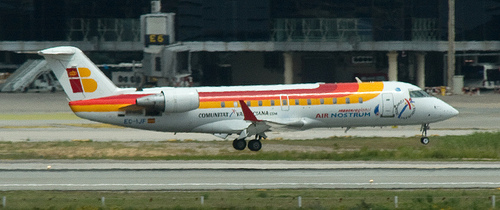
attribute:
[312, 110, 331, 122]
air — red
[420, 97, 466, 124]
nose — pointy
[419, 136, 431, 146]
wheel — plane, down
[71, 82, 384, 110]
stripe — yellow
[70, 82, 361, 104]
stripe — red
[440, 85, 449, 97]
can — yellow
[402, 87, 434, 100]
window — wraparound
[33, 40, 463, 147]
plane — landing, white, taking off, from spain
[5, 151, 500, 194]
runway — for plane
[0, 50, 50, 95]
ramp — empty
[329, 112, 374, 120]
writing — blue, air nostrum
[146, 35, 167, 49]
letters — yellow